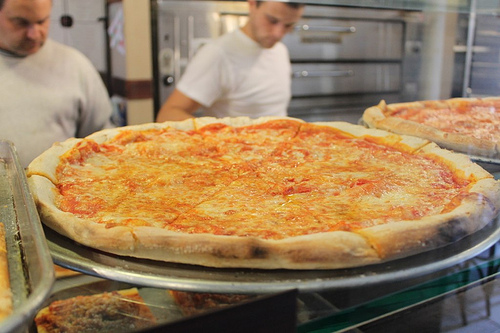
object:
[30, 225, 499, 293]
pan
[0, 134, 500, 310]
shelf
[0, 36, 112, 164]
shirt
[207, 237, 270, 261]
burn marks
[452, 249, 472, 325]
legs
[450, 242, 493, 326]
chair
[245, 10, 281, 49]
beard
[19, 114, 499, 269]
pizza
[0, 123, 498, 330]
table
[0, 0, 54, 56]
head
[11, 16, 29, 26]
eye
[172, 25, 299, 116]
t-shirt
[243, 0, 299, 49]
head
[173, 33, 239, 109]
shoulder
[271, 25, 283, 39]
nose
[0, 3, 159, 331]
left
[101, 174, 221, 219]
cheese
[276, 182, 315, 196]
sauce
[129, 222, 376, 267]
crust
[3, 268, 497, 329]
window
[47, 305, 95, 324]
sauce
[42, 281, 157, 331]
slice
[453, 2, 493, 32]
trays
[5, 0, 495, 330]
kitchen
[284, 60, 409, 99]
door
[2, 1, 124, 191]
man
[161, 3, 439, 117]
oven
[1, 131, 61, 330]
pan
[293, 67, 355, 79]
handle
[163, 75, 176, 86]
knob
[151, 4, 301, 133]
man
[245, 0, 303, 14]
hair